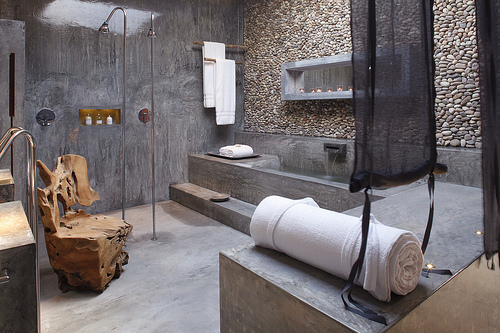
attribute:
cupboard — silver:
[217, 182, 498, 329]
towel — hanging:
[216, 57, 238, 123]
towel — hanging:
[201, 40, 222, 105]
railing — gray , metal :
[1, 125, 54, 325]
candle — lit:
[296, 87, 306, 94]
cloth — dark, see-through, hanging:
[346, 6, 443, 188]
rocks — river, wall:
[433, 2, 478, 147]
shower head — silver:
[146, 13, 168, 242]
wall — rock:
[248, 40, 283, 109]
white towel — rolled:
[243, 185, 439, 305]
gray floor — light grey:
[39, 199, 248, 331]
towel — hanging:
[202, 55, 235, 126]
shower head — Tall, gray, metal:
[95, 4, 130, 226]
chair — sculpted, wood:
[35, 153, 135, 285]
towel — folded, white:
[217, 142, 254, 159]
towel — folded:
[217, 140, 259, 161]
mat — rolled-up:
[240, 167, 440, 322]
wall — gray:
[431, 1, 483, 148]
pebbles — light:
[441, 53, 466, 69]